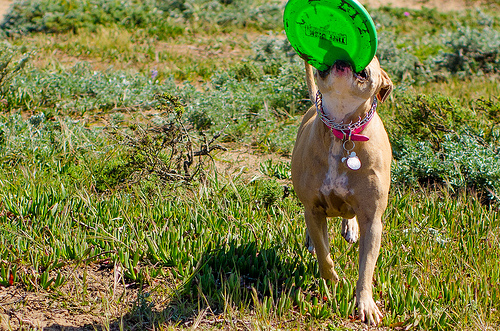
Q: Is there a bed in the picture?
A: No, there are no beds.